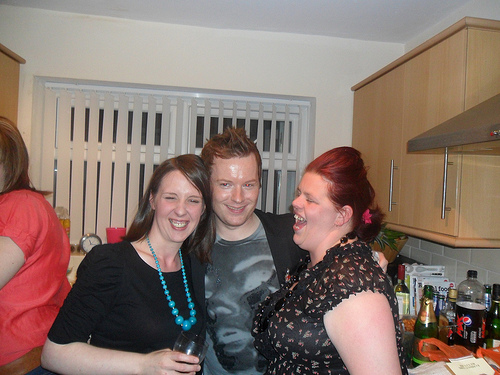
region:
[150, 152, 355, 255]
they are happy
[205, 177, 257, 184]
the pupils are red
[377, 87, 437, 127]
the cupboard is wooden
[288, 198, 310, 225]
the lady is laughing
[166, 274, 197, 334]
blue pearls necklace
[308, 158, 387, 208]
the hair is brown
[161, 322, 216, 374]
the lady is holdin a glass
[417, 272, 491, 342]
bottles on the rack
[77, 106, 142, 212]
the curtain is drawn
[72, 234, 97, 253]
the clock has a lining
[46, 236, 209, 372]
Woman wearing a dress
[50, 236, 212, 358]
Woman wearing a black dress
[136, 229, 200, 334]
Woman wearing a necklace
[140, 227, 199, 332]
Woman wearing a blue necklace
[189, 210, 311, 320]
Man wearing a blazer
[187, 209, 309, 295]
Man wearing a black blazer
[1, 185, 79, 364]
Woman wearing a shirt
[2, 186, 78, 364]
Woman wearing a red shirt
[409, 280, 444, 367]
Bottle of champagne on counter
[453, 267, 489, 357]
Bottle of soda on counter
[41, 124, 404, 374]
Man with arms around two women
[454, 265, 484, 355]
Bottle of Pepsi on the counter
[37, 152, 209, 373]
Woman holding glass in her hand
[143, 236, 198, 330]
Blue beads around woman's neck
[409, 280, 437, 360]
Open bottle of champagne on counter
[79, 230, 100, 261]
Block on the windowsill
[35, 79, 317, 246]
Vertical blinds over window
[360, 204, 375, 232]
Red scrunchie in woman's hair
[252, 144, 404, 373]
Red-haired woman in black short-sleeve top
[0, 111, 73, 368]
Back of woman wearing a red dress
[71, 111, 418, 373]
tree people standing in a kitchen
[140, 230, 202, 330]
necklace around a neck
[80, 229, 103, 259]
clock on the window sill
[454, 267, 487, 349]
soda bottle on the counter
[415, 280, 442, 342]
bottle on the counter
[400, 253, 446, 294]
books on the counter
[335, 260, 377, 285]
flowers on a blouse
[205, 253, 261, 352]
face on a shirt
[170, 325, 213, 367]
glass in the woman's hand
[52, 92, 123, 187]
blinds on the windows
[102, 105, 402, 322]
three people laughing together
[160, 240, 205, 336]
blue necklace on girl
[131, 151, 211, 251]
head of the girl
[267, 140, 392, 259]
girl with eyes closed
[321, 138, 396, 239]
red hair of the girl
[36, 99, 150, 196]
blinds on the window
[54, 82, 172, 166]
window behind the people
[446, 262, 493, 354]
drink on the counter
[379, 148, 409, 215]
silver handle of the cabinet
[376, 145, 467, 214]
two cabinets next to each other